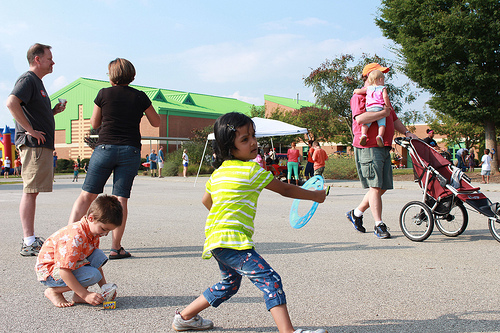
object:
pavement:
[316, 241, 394, 331]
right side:
[365, 1, 500, 333]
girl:
[353, 71, 392, 148]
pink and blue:
[362, 86, 388, 128]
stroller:
[394, 137, 500, 242]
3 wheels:
[399, 196, 500, 242]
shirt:
[201, 159, 275, 259]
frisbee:
[289, 175, 325, 229]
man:
[6, 42, 65, 257]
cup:
[58, 98, 66, 109]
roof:
[83, 77, 316, 117]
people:
[253, 140, 328, 186]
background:
[0, 0, 500, 163]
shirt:
[93, 84, 151, 149]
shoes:
[345, 209, 390, 239]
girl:
[170, 112, 326, 333]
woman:
[68, 59, 162, 260]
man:
[345, 62, 418, 239]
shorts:
[19, 144, 54, 193]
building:
[0, 75, 469, 174]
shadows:
[94, 228, 500, 333]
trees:
[370, 0, 499, 173]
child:
[34, 194, 123, 308]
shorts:
[82, 144, 142, 198]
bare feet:
[44, 289, 89, 308]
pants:
[354, 147, 395, 191]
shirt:
[35, 213, 100, 281]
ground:
[0, 175, 500, 333]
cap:
[362, 63, 390, 78]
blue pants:
[362, 106, 386, 127]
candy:
[99, 281, 117, 309]